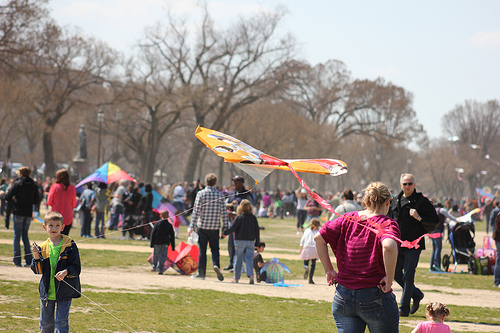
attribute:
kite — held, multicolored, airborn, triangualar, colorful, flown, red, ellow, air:
[199, 123, 344, 195]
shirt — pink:
[316, 208, 391, 301]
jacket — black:
[398, 196, 437, 250]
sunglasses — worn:
[398, 181, 424, 188]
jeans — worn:
[329, 280, 409, 332]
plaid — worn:
[198, 187, 227, 234]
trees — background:
[17, 29, 393, 122]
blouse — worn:
[297, 229, 321, 258]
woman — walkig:
[231, 197, 263, 281]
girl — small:
[404, 307, 469, 330]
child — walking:
[296, 218, 324, 274]